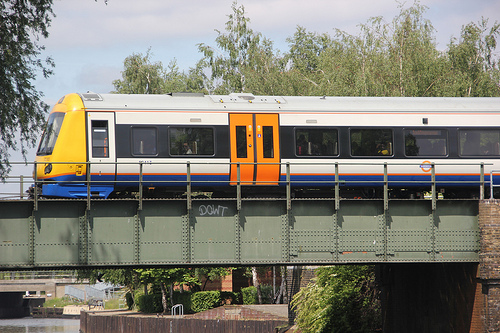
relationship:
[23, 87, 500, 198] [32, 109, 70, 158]
train has windshield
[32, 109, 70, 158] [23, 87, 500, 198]
windshield in front of train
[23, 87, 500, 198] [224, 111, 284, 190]
train has door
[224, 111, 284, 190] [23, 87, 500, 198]
door in front of train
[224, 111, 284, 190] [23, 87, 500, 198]
door on train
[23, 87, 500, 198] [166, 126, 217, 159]
train has passenger window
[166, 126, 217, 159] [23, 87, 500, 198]
passenger window on side of train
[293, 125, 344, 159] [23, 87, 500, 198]
passenger window on side of train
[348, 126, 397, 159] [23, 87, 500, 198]
passenger window on side of train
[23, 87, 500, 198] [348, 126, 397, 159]
train has passenger window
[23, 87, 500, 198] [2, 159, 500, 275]
train goes across bridge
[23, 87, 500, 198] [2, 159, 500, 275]
train crosses bridge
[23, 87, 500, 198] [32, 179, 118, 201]
train has bumper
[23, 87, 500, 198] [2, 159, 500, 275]
train travels over bridge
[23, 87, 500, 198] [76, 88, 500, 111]
train has roof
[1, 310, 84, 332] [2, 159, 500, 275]
water below bridge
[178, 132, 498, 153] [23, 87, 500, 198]
people inside train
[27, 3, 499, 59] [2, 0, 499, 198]
clouds in sky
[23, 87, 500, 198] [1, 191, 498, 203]
train on tracks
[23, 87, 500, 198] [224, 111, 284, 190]
train has doors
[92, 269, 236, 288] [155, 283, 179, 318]
leaves on tree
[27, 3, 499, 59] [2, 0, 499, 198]
clouds are in sky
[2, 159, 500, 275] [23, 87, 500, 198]
bridge under train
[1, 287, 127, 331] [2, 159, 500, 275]
canal below bridge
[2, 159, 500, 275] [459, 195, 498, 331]
bridge has brick base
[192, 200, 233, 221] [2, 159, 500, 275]
graffiti on bridge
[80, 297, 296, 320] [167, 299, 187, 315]
dock has rails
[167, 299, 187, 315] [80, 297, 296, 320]
rails on dock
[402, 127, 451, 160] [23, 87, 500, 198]
passenger window on side of train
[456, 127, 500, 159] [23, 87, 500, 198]
passenger window on side of train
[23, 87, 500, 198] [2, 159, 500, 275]
train crossing bridge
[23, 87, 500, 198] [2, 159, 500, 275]
train crossing over bridge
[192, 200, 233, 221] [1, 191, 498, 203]
graffiti under tracks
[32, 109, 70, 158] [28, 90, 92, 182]
windshield on train front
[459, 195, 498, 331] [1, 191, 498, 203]
brick base supports tracks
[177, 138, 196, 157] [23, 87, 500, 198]
passenger in train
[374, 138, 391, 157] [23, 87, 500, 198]
passenger in train